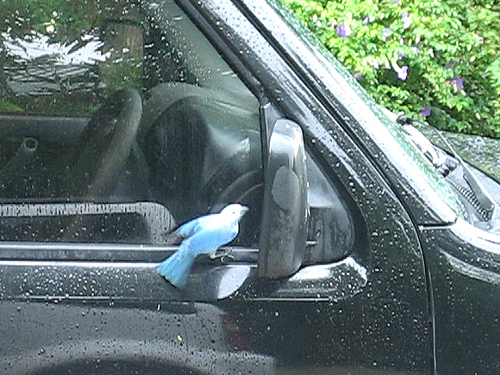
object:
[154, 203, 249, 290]
bird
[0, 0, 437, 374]
door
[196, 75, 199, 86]
rain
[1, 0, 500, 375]
car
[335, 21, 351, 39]
flowers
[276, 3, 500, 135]
bushes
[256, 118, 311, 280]
mirror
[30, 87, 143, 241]
steering wheel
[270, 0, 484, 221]
windshield wiper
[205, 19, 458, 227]
paint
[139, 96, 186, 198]
dashboard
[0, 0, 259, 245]
window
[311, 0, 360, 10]
bush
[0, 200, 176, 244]
knob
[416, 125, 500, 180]
hood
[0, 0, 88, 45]
leaves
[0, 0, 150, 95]
reflection